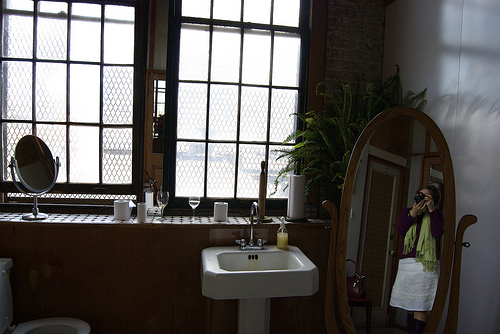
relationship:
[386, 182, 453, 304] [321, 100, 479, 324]
person in mirror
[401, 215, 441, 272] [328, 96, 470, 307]
scarf on mirror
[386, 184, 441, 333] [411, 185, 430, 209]
person with camera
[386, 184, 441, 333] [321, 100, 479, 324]
person in mirror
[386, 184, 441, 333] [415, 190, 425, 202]
person holding camera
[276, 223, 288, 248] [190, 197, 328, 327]
bottle next to sink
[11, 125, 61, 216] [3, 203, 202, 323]
mirror on counter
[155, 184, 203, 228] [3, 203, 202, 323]
wine glasses on counter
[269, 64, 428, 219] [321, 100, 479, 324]
plant partially behind mirror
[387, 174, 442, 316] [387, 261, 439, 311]
reflection of skirt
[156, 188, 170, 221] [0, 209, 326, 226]
wine glass on ledge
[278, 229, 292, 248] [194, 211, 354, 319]
bottle on sink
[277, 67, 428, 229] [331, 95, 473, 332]
plant behind mirror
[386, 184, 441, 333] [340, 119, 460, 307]
person in mirror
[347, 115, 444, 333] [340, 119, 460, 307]
reflection in mirror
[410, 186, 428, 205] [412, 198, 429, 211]
camera in hand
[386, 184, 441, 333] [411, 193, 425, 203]
person taking picture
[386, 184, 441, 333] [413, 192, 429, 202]
person holding camera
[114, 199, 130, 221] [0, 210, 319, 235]
paper on shelf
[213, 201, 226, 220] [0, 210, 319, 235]
toilet paper on shelf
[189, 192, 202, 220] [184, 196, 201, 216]
glass has liquid